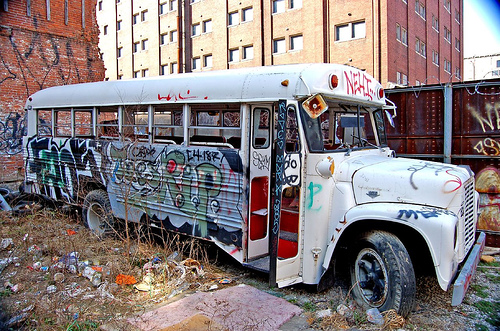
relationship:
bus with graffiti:
[29, 41, 425, 256] [2, 17, 96, 94]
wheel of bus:
[326, 230, 414, 323] [29, 41, 425, 256]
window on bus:
[176, 104, 261, 137] [29, 41, 425, 256]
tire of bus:
[342, 211, 425, 317] [29, 41, 425, 256]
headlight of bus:
[316, 151, 364, 182] [29, 41, 425, 256]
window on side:
[176, 104, 261, 137] [120, 72, 263, 150]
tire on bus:
[342, 211, 425, 317] [29, 41, 425, 256]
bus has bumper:
[29, 41, 425, 256] [415, 209, 499, 295]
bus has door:
[29, 41, 425, 256] [236, 175, 314, 267]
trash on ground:
[18, 219, 200, 321] [28, 188, 162, 289]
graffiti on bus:
[24, 133, 244, 254] [29, 41, 425, 256]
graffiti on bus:
[2, 17, 96, 94] [29, 41, 425, 256]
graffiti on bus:
[56, 145, 198, 220] [29, 41, 425, 256]